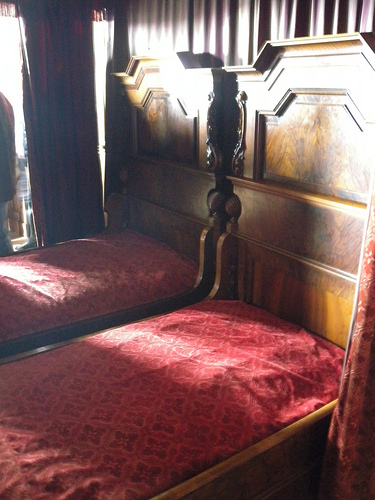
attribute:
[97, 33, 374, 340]
bed post — brown, wooden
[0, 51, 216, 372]
bed — twin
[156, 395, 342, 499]
frame — wooden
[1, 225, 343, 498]
pattern — diamond, red, of diamond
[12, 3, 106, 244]
curtain — dark, red, brown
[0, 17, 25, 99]
sky — gray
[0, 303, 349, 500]
sheet — red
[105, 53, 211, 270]
head board — brown, wooden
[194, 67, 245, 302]
finials — wooden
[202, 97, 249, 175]
carving — floral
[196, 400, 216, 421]
floral designs — four, red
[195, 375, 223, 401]
designs — floral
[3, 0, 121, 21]
fringes — red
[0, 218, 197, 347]
bed sheet — red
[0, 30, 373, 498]
bed — vintage, twins, each other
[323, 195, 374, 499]
drapes — red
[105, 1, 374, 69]
drapes — brown, dark red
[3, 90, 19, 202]
shirt — red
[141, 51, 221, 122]
sunlight — reflecting